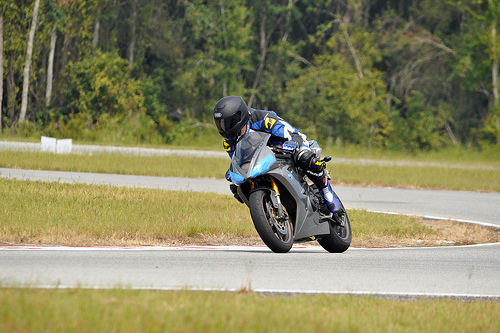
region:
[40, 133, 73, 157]
white sign near road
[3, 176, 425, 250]
grass next to road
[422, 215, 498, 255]
grass near curve is brown and dry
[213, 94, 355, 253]
person riding motorcycle on a paved road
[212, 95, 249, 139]
person wearing a black helmet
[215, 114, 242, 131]
visor on helmet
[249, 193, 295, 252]
black tires on motorcycle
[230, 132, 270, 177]
clear windshield on motorcycle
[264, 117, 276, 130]
yellow patch on jacket sleeve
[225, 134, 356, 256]
motorcycle under person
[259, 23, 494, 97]
The trees are green.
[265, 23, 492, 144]
The trees are leafy.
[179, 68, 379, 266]
The man is riding a motorcycle.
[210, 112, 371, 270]
The bike is blue.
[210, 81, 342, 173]
His helmet is black.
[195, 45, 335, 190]
The man is wearing a blue jacket.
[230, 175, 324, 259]
The tire is black.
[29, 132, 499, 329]
The road is curved.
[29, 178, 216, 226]
The grass is dying.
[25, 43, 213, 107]
The trunks are skinny.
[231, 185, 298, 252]
Front tire of bike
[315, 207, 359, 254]
Back tire of bike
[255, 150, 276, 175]
Right light blue stripe on bike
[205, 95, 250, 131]
Black helmet on man's head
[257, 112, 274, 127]
Yellow patch on man's shirt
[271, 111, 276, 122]
Black out lining of yellow patch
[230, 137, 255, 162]
Clear bike windshield window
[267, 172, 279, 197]
Orange pole in connection to tire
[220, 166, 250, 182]
Left light blue strip on bike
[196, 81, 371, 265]
Man with helmet riding bike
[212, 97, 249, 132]
Black helmet on a man's head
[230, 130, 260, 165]
Windshield on a motorcycle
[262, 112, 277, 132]
Yellow patch on a man's jacket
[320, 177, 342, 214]
Man wearing a blue boot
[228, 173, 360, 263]
Wheels of motorcycle on the road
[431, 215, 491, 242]
Patch of brown grass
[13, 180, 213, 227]
Green grass next to a road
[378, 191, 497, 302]
Curve in the road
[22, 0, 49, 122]
White tree trunk in the woods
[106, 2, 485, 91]
Trees with green leaves behind a road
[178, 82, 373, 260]
Person riding a motorcycle.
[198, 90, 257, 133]
The person is wearing a helmet.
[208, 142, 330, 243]
The motorcycle is grey and blue.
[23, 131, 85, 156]
Two signs on the ground.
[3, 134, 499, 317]
The road is curved.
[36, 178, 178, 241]
The grass is dry.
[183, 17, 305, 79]
The trees are green.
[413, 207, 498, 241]
White on the edge of the road.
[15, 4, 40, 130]
The tree trunk is grey.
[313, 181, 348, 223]
The shoe is blue and white.